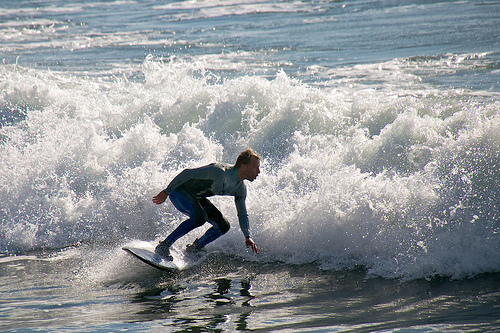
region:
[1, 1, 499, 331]
The man is on a surfboard.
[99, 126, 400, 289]
The man is wearing a wetsuit.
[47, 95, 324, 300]
The surfboard is in the water.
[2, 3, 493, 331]
The water is splashing.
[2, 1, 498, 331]
The water is vigorous.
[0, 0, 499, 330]
The water is turbulent.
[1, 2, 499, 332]
The water is tumultuous.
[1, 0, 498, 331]
The water is lively.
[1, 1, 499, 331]
The water is spirited.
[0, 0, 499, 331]
The water is zealous.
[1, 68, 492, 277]
a large wave breaking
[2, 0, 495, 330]
blue ocean water with waves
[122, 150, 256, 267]
a surfer riding a wave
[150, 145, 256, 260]
surfer in a blue and green wetsuit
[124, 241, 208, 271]
white surfboard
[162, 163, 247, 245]
blue and green wetsuit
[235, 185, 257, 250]
surfer's left hand reaching down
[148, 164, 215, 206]
the surfer's right arm tucked behind him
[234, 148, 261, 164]
the surfer's blonde hair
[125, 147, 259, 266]
blonde surfer on a white board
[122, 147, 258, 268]
a man surfing on the ocean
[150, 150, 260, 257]
a man standing on a surfboard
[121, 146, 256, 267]
a man surfing in front of a wave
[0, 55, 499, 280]
a huge wave in the ocean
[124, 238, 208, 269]
a white surfboard on the water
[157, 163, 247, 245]
man wearing a wet suit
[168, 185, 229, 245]
man wearing blue and black wet pants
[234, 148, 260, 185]
man with short blond hair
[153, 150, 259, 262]
man keeping his balance on a surfboard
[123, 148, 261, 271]
man on a surfboard on the ocean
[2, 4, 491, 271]
The wave is splashing.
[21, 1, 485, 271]
He is in the ocean.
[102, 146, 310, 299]
He is surfing.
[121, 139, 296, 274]
He is wearing a wet suit.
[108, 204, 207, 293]
His surf board is white.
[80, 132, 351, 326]
He is standing on the board.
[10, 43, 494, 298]
He is wet.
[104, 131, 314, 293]
He is balancing.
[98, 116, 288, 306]
He is touching the water.